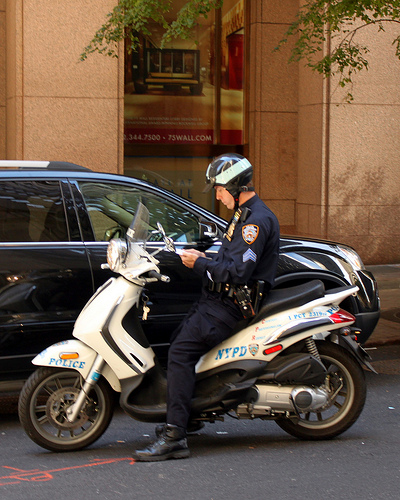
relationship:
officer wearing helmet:
[126, 149, 283, 463] [202, 153, 262, 190]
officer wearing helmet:
[126, 149, 283, 463] [198, 152, 259, 213]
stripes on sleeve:
[237, 239, 263, 271] [184, 209, 284, 287]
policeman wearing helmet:
[166, 150, 274, 440] [199, 149, 254, 193]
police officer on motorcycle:
[130, 151, 280, 463] [19, 203, 373, 449]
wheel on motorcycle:
[12, 369, 119, 460] [19, 203, 373, 449]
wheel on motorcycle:
[263, 338, 368, 446] [19, 203, 373, 449]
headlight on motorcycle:
[103, 239, 125, 271] [19, 203, 373, 449]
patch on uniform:
[239, 248, 262, 267] [212, 209, 273, 276]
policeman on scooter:
[166, 150, 274, 440] [10, 192, 373, 456]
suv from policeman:
[0, 157, 382, 407] [166, 150, 274, 440]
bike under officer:
[17, 198, 383, 447] [126, 149, 283, 463]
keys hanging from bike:
[138, 293, 152, 324] [17, 198, 383, 447]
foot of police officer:
[132, 418, 192, 460] [130, 151, 280, 463]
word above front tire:
[46, 355, 86, 371] [16, 360, 113, 452]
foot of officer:
[109, 408, 197, 472] [99, 147, 363, 390]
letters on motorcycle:
[206, 337, 248, 359] [19, 203, 373, 449]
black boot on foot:
[129, 418, 190, 465] [126, 420, 196, 466]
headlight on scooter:
[103, 234, 134, 271] [10, 192, 373, 456]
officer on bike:
[126, 149, 283, 463] [17, 198, 383, 447]